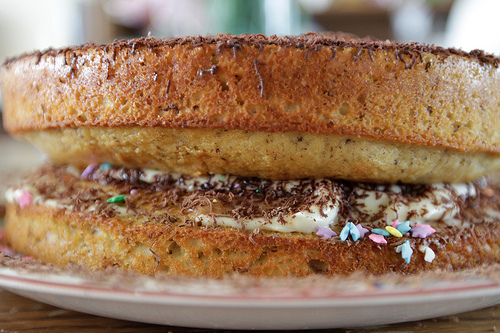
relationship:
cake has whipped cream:
[2, 32, 499, 298] [17, 165, 499, 233]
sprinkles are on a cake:
[108, 194, 125, 202] [2, 32, 499, 298]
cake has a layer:
[2, 32, 499, 298] [2, 37, 496, 189]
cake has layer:
[2, 32, 499, 298] [2, 37, 496, 189]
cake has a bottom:
[2, 32, 499, 298] [3, 192, 499, 284]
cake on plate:
[2, 32, 499, 298] [1, 268, 498, 330]